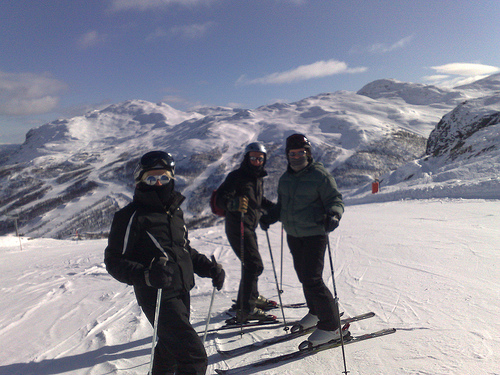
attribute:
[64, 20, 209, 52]
clouds — white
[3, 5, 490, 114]
sky — blue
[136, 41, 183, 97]
clouds — white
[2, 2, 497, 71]
sky — blue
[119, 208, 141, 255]
stripe — reflective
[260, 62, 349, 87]
cloud — white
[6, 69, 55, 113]
cloud — white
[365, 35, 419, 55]
cloud — white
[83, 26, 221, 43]
cloud — white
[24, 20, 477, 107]
sky — blue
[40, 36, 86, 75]
clouds — white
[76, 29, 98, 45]
cloud — white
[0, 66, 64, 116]
cloud — white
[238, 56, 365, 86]
cloud — white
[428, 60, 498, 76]
cloud — white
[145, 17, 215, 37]
cloud — white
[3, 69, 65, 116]
clouds — white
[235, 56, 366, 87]
clouds — white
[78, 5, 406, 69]
sky — blue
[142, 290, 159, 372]
ski pole — silver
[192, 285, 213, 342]
ski pole — silver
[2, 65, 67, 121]
cloud — white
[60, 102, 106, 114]
cloud — white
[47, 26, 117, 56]
cloud — white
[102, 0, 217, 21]
cloud — white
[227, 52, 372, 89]
cloud — white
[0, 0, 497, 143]
sky — blue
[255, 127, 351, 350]
skier — male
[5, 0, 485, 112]
clouds — white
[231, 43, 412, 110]
clouds — white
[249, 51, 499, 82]
clouds — blue, white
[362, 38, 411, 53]
cloud — white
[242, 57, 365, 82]
cloud — white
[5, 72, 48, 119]
cloud — white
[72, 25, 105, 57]
cloud — white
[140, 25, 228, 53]
cloud — white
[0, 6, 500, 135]
sky — blue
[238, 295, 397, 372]
gray skis — pair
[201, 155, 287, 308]
outfit — black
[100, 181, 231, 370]
outfit — black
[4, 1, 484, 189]
sky — blue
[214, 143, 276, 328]
skier — male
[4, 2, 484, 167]
sky — blue